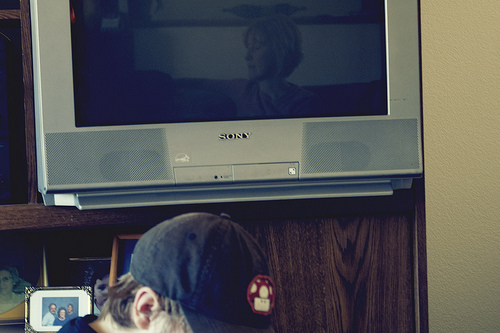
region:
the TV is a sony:
[220, 122, 252, 144]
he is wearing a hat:
[172, 212, 269, 302]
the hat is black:
[117, 186, 306, 321]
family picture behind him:
[28, 283, 98, 328]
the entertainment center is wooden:
[175, 213, 403, 273]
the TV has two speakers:
[66, 123, 389, 188]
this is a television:
[17, 0, 462, 237]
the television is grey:
[8, 5, 457, 243]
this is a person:
[54, 190, 306, 331]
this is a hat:
[109, 198, 323, 330]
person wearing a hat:
[90, 165, 314, 330]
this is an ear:
[117, 284, 192, 331]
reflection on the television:
[106, 10, 371, 139]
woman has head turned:
[211, 11, 316, 112]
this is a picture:
[16, 267, 94, 329]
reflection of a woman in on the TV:
[222, 11, 304, 108]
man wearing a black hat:
[118, 200, 268, 330]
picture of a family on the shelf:
[17, 282, 104, 328]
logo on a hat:
[244, 275, 279, 317]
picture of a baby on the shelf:
[76, 272, 121, 305]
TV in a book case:
[22, 8, 446, 210]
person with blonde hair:
[93, 272, 154, 316]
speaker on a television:
[41, 129, 166, 191]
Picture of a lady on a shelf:
[0, 236, 57, 325]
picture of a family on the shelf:
[23, 278, 95, 331]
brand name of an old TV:
[215, 126, 253, 142]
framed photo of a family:
[22, 285, 92, 330]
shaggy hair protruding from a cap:
[92, 269, 136, 328]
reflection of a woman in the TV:
[227, 10, 319, 122]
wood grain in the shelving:
[258, 218, 415, 331]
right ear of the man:
[127, 285, 157, 328]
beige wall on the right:
[420, 1, 499, 326]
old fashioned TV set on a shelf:
[22, 0, 423, 208]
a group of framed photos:
[1, 225, 141, 331]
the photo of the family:
[41, 295, 79, 327]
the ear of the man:
[133, 290, 159, 329]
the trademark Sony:
[219, 131, 249, 141]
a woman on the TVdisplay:
[241, 25, 303, 110]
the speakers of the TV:
[46, 120, 418, 180]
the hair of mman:
[96, 277, 179, 322]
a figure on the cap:
[248, 276, 275, 310]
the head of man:
[49, 302, 55, 312]